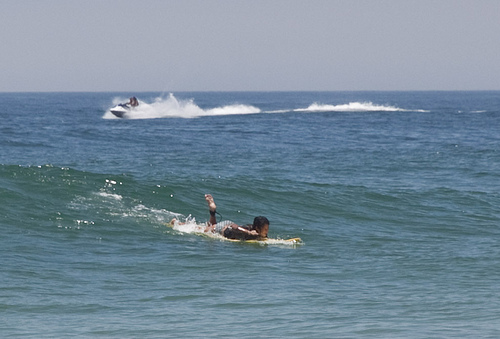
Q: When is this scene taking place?
A: Daytime.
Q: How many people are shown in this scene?
A: Two.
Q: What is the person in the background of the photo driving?
A: Jetski.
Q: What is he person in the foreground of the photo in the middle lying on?
A: Surfboard.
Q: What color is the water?
A: Blue.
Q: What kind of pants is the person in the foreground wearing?
A: Shorts.